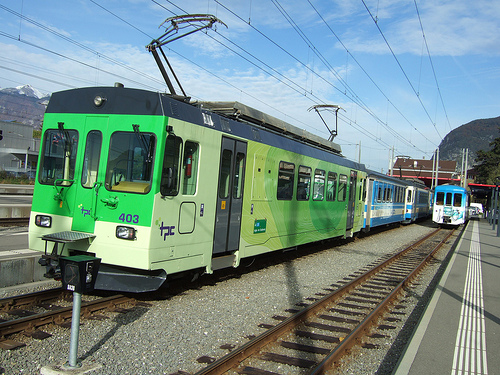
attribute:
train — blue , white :
[373, 169, 473, 236]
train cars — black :
[30, 81, 432, 302]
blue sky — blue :
[0, 0, 498, 196]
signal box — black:
[41, 248, 111, 373]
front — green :
[31, 109, 166, 229]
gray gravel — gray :
[6, 219, 449, 368]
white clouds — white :
[262, 36, 357, 103]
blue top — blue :
[431, 178, 471, 201]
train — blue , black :
[20, 79, 381, 300]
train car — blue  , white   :
[359, 159, 446, 239]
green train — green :
[28, 84, 369, 302]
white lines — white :
[457, 210, 485, 373]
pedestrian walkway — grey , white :
[398, 216, 498, 373]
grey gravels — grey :
[115, 313, 194, 349]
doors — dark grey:
[213, 128, 242, 261]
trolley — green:
[19, 73, 375, 303]